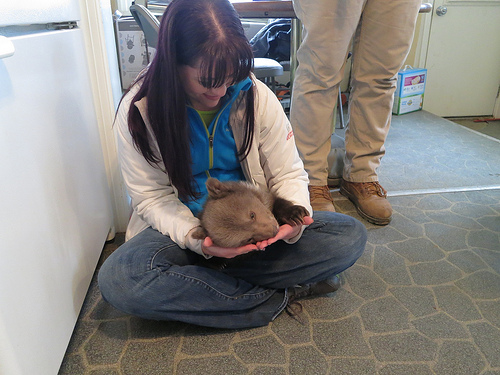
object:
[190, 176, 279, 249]
head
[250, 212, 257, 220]
eye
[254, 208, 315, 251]
paw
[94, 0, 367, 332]
woman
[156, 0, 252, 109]
head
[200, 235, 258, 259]
hand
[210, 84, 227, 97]
nose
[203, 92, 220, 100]
mouth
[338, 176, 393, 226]
boot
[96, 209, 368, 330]
jeans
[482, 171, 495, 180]
stone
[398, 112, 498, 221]
floor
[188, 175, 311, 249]
bear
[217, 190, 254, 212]
fleece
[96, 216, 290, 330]
legs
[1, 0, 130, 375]
fridge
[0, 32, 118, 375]
door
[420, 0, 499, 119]
door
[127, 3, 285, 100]
chair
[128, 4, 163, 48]
back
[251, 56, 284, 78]
front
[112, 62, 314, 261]
jacket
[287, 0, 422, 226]
person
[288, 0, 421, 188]
pants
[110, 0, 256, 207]
hair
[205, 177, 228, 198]
ears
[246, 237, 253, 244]
eyes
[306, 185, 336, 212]
shoes